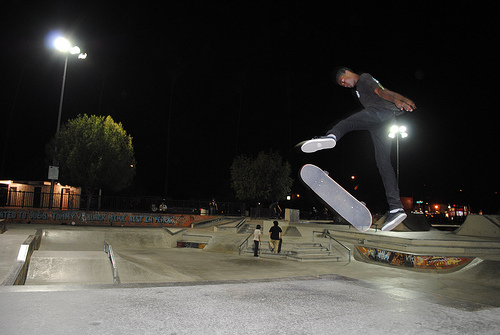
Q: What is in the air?
A: Skateboarder.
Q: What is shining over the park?
A: The street light.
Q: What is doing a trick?
A: The skateboarder.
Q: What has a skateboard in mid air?
A: The man.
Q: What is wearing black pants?
A: The man.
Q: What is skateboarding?
A: The man.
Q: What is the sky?
A: Dark.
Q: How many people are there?
A: Three.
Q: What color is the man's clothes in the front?
A: Black.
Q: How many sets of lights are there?
A: Two.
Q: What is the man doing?
A: Skateboarding.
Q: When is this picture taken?
A: At night.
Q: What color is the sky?
A: Black.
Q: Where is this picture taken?
A: At a s.